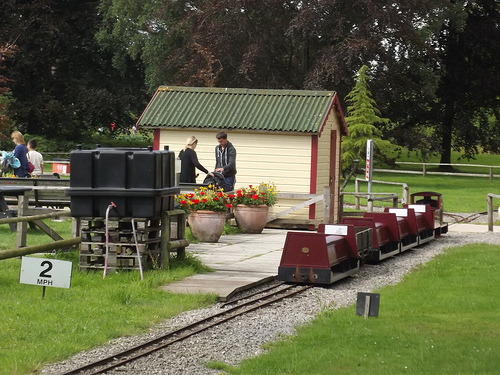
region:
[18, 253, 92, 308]
black and white sign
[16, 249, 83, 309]
sign sticking in the grass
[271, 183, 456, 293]
small kiddie train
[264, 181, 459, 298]
kiddie train on the tracks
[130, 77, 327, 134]
green roof on the building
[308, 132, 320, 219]
the corner of the building is red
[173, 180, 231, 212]
red and yellow flowers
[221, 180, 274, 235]
flowers in a planter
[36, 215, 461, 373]
gravel along the tracks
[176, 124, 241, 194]
a man and a woman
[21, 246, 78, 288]
the number is two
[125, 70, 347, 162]
the roof if green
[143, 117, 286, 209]
two person near home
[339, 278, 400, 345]
a object in ground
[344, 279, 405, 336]
a object in grass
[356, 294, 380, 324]
handle of the object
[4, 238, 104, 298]
a display of board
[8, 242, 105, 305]
a number in the board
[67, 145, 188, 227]
three set of boxes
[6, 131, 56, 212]
two people walking away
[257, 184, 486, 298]
a small train in track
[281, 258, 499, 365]
a view of green grass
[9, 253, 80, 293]
speed sign by children's train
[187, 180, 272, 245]
large pots with flowers in them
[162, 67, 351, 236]
small building by the train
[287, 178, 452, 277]
red train on the tracks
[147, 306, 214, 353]
small train track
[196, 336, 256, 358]
gravel by the train tracks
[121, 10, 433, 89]
trees behind the building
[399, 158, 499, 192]
wooden fence around the yard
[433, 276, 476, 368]
green grass near the train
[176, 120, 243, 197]
people standing by the building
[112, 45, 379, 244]
this is a house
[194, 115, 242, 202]
this is a person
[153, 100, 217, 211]
this is a person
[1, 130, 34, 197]
this is a person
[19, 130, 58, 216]
this is a person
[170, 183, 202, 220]
these are red flowers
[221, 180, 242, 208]
these are red flowers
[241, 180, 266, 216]
these are red flowers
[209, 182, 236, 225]
these are red flowers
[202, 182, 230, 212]
these are red flowers